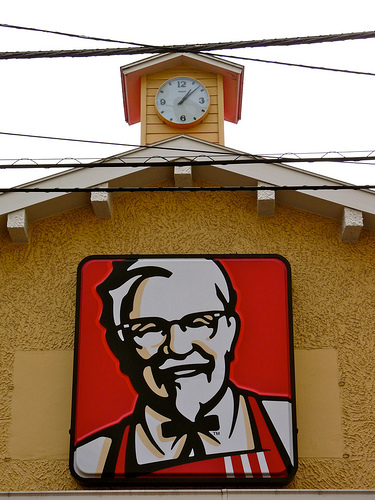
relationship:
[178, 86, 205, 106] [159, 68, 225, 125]
hands on clock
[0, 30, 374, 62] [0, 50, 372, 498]
rope on top of building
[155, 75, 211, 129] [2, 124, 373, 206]
clock on top of roof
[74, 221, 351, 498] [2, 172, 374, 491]
frame on wall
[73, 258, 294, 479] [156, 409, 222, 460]
comic person has neck tie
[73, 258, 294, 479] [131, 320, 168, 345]
comic person has eye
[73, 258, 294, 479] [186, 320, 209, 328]
comic person has eye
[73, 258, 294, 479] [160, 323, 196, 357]
comic person has nose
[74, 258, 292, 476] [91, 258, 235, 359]
comic person has hair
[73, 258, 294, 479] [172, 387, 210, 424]
comic person has beard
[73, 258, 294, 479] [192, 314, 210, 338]
comic person has eye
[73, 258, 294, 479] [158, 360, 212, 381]
comic person has mouth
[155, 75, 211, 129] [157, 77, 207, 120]
clock has face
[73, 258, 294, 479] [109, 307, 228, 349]
comic person wearing glasses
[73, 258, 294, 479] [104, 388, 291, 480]
comic person wearing apron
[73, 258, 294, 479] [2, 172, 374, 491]
comic person on wall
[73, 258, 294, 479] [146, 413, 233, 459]
comic person wearing bowtie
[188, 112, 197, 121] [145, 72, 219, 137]
5 on clock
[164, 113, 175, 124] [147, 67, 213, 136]
7 on clock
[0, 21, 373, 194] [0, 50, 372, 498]
wires hanging over building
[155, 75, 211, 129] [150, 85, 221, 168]
clock shows 1:08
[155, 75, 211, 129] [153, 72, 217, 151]
clock shows 1:08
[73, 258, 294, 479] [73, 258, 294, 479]
comic person of a comic person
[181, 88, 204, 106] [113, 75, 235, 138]
hands of a clock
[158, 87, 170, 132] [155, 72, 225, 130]
number on a clock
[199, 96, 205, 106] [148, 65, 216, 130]
3 on a clock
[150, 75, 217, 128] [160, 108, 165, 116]
clock has number 8